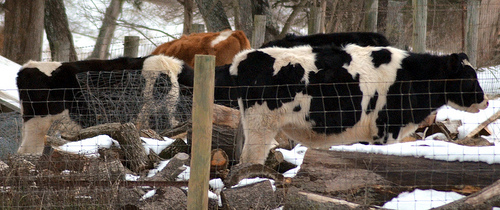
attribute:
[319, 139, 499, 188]
log — large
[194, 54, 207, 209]
fence pole — wood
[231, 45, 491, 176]
cow — black, white, standing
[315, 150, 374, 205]
terrain — rocky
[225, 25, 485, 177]
cow — black, white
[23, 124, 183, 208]
ground — long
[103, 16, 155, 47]
trees — bare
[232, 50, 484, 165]
cow — brown, white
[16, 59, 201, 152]
cow — brown, white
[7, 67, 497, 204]
fence — brown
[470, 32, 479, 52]
wall — wooden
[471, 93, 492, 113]
mouth — white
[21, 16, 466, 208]
fence — metal, wire, supported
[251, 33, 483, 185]
cow — white 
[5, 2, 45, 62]
tree trunk — brown, grey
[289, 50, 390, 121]
spots — black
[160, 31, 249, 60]
cow — standing, brown, white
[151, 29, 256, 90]
cow — brown, white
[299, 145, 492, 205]
log — snow covered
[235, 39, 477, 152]
cow — black, white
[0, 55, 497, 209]
fence — wire, mesh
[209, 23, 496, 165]
cow — black, white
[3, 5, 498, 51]
trees — lining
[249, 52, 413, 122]
cow — black, white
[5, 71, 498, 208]
wire — metal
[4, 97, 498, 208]
ground — rocky